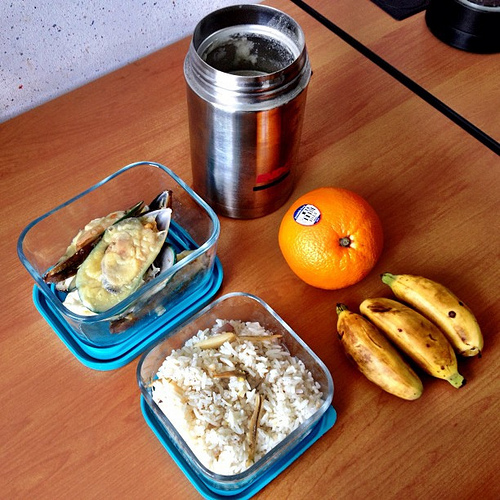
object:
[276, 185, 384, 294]
orange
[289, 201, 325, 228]
sticker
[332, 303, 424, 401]
bananas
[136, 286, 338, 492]
bowl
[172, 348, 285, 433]
rice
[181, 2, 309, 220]
container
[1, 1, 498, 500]
table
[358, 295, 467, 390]
plantain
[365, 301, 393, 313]
mark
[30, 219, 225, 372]
cover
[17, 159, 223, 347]
container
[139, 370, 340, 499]
cover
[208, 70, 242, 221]
reflection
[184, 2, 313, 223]
metal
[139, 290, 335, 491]
rim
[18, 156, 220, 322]
rim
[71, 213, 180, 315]
food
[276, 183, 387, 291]
fruit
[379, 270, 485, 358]
banana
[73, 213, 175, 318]
oysters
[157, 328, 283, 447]
food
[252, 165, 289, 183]
lettering